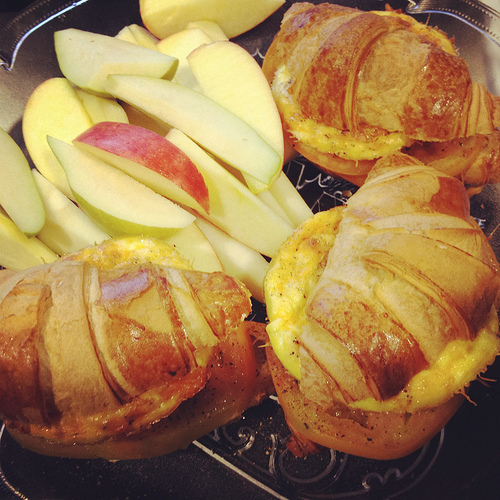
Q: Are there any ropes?
A: No, there are no ropes.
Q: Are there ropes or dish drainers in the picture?
A: No, there are no ropes or dish drainers.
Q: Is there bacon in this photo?
A: Yes, there is bacon.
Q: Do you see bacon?
A: Yes, there is bacon.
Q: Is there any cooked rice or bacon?
A: Yes, there is cooked bacon.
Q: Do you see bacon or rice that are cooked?
A: Yes, the bacon is cooked.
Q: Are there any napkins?
A: No, there are no napkins.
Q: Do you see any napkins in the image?
A: No, there are no napkins.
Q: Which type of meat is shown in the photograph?
A: The meat is bacon.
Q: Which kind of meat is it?
A: The meat is bacon.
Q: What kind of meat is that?
A: This is bacon.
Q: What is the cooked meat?
A: The meat is bacon.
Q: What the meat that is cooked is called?
A: The meat is bacon.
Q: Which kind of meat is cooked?
A: The meat is bacon.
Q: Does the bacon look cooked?
A: Yes, the bacon is cooked.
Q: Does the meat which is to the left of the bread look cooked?
A: Yes, the bacon is cooked.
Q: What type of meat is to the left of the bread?
A: The meat is bacon.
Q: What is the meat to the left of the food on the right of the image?
A: The meat is bacon.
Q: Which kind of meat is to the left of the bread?
A: The meat is bacon.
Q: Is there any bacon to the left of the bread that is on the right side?
A: Yes, there is bacon to the left of the bread.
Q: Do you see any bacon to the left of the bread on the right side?
A: Yes, there is bacon to the left of the bread.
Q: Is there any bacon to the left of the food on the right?
A: Yes, there is bacon to the left of the bread.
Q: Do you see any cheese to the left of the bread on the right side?
A: No, there is bacon to the left of the bread.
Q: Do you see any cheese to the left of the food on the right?
A: No, there is bacon to the left of the bread.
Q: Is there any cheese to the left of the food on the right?
A: No, there is bacon to the left of the bread.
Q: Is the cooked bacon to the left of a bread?
A: Yes, the bacon is to the left of a bread.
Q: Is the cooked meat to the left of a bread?
A: Yes, the bacon is to the left of a bread.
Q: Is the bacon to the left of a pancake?
A: No, the bacon is to the left of a bread.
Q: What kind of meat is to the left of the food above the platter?
A: The meat is bacon.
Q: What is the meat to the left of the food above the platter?
A: The meat is bacon.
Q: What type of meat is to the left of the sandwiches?
A: The meat is bacon.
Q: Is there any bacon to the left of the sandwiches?
A: Yes, there is bacon to the left of the sandwiches.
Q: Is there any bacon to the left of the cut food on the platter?
A: Yes, there is bacon to the left of the sandwiches.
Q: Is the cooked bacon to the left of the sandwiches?
A: Yes, the bacon is to the left of the sandwiches.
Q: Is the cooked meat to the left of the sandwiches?
A: Yes, the bacon is to the left of the sandwiches.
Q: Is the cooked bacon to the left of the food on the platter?
A: Yes, the bacon is to the left of the sandwiches.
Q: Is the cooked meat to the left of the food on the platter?
A: Yes, the bacon is to the left of the sandwiches.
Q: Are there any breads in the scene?
A: Yes, there is a bread.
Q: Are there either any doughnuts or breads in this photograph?
A: Yes, there is a bread.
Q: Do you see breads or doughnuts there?
A: Yes, there is a bread.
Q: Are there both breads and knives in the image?
A: No, there is a bread but no knives.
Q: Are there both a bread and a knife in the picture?
A: No, there is a bread but no knives.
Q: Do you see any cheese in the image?
A: No, there is no cheese.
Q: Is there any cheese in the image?
A: No, there is no cheese.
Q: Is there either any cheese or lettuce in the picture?
A: No, there are no cheese or lettuce.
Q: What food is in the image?
A: The food is a bread.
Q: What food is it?
A: The food is a bread.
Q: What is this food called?
A: That is a bread.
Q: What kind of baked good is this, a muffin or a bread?
A: That is a bread.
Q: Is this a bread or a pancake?
A: This is a bread.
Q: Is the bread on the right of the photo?
A: Yes, the bread is on the right of the image.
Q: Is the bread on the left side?
A: No, the bread is on the right of the image.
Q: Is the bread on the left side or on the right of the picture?
A: The bread is on the right of the image.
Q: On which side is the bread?
A: The bread is on the right of the image.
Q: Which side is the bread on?
A: The bread is on the right of the image.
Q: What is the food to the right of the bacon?
A: The food is a bread.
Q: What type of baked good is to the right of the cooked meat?
A: The food is a bread.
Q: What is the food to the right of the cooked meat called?
A: The food is a bread.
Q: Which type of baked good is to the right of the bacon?
A: The food is a bread.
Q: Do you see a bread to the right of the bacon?
A: Yes, there is a bread to the right of the bacon.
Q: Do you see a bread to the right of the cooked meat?
A: Yes, there is a bread to the right of the bacon.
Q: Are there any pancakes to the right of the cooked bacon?
A: No, there is a bread to the right of the bacon.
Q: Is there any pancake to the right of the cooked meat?
A: No, there is a bread to the right of the bacon.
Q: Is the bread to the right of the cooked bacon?
A: Yes, the bread is to the right of the bacon.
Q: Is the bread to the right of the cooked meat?
A: Yes, the bread is to the right of the bacon.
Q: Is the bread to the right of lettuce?
A: No, the bread is to the right of the bacon.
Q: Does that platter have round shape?
A: Yes, the platter is round.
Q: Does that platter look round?
A: Yes, the platter is round.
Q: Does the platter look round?
A: Yes, the platter is round.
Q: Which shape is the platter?
A: The platter is round.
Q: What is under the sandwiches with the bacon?
A: The platter is under the sandwiches.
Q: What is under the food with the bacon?
A: The platter is under the sandwiches.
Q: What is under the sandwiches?
A: The platter is under the sandwiches.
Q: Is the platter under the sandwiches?
A: Yes, the platter is under the sandwiches.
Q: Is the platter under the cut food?
A: Yes, the platter is under the sandwiches.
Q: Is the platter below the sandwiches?
A: Yes, the platter is below the sandwiches.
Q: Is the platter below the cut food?
A: Yes, the platter is below the sandwiches.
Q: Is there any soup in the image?
A: No, there is no soup.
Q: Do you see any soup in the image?
A: No, there is no soup.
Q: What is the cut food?
A: The food is sandwiches.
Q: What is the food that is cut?
A: The food is sandwiches.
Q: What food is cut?
A: The food is sandwiches.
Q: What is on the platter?
A: The sandwiches are on the platter.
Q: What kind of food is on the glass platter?
A: The food is sandwiches.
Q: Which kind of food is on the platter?
A: The food is sandwiches.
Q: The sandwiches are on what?
A: The sandwiches are on the platter.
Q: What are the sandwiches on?
A: The sandwiches are on the platter.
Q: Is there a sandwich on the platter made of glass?
A: Yes, there are sandwiches on the platter.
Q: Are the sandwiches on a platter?
A: Yes, the sandwiches are on a platter.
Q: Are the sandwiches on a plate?
A: No, the sandwiches are on a platter.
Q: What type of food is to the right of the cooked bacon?
A: The food is sandwiches.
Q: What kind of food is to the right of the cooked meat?
A: The food is sandwiches.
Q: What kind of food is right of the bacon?
A: The food is sandwiches.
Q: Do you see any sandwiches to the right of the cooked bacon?
A: Yes, there are sandwiches to the right of the bacon.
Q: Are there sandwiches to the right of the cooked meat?
A: Yes, there are sandwiches to the right of the bacon.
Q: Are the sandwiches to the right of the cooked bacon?
A: Yes, the sandwiches are to the right of the bacon.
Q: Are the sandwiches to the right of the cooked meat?
A: Yes, the sandwiches are to the right of the bacon.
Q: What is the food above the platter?
A: The food is sandwiches.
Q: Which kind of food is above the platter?
A: The food is sandwiches.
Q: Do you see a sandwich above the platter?
A: Yes, there are sandwiches above the platter.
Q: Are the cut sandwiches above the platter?
A: Yes, the sandwiches are above the platter.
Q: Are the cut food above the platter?
A: Yes, the sandwiches are above the platter.